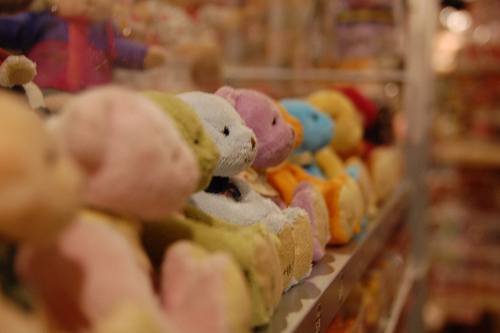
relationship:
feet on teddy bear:
[370, 146, 405, 201] [337, 79, 399, 201]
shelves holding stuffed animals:
[0, 0, 498, 331] [5, 84, 388, 318]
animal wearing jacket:
[3, 10, 160, 77] [234, 168, 284, 197]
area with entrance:
[418, 14, 493, 320] [413, 13, 437, 240]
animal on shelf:
[0, 88, 391, 333] [271, 180, 405, 326]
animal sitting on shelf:
[0, 88, 391, 333] [302, 175, 433, 328]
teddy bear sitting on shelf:
[284, 90, 338, 185] [287, 185, 412, 332]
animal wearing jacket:
[0, 88, 391, 333] [132, 211, 202, 262]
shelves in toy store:
[0, 0, 498, 331] [0, 0, 498, 331]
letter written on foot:
[280, 263, 296, 278] [261, 227, 312, 273]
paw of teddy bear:
[142, 41, 167, 71] [3, 4, 166, 91]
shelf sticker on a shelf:
[335, 276, 348, 301] [259, 181, 409, 331]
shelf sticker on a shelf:
[310, 303, 324, 328] [259, 181, 409, 331]